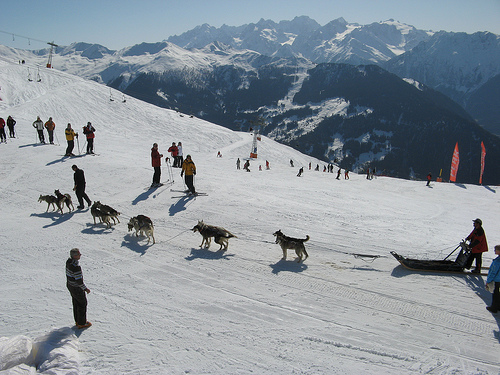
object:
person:
[30, 114, 47, 146]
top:
[28, 117, 46, 130]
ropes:
[48, 187, 397, 266]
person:
[483, 244, 499, 343]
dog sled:
[388, 217, 482, 278]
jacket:
[179, 160, 196, 176]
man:
[462, 218, 486, 275]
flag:
[448, 141, 459, 183]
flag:
[477, 142, 487, 179]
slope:
[1, 53, 496, 373]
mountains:
[0, 0, 497, 185]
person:
[459, 214, 491, 275]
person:
[64, 247, 95, 326]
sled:
[390, 250, 462, 274]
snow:
[9, 61, 498, 373]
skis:
[173, 187, 208, 199]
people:
[148, 140, 164, 192]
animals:
[37, 191, 71, 216]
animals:
[92, 199, 121, 227]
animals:
[125, 214, 157, 246]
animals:
[188, 222, 239, 254]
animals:
[271, 229, 311, 259]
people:
[178, 154, 199, 202]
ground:
[5, 63, 490, 367]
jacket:
[483, 257, 497, 295]